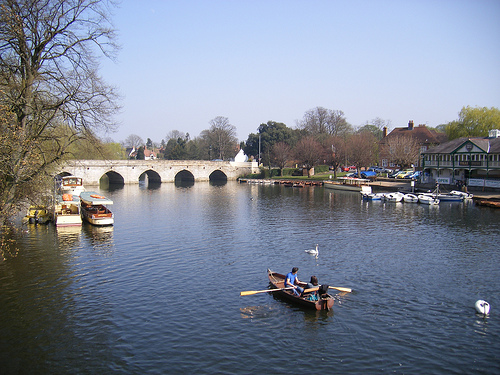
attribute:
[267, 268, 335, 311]
boat — small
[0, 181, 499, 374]
water — calm, rippling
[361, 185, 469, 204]
boats — grouped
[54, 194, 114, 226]
boats — brown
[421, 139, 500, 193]
building — white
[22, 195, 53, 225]
boat — yellow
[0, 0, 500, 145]
sky — clear, blue